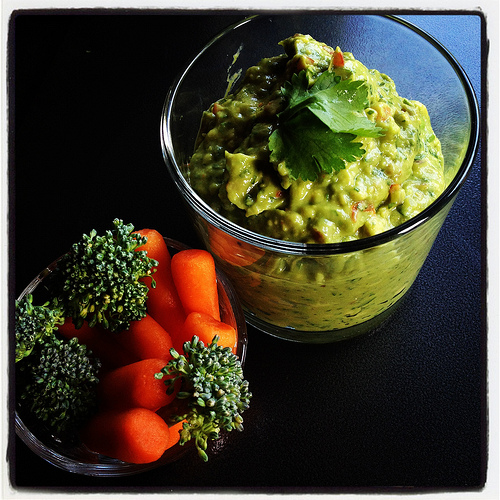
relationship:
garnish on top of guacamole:
[252, 64, 399, 185] [200, 27, 445, 335]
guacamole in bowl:
[188, 34, 448, 336] [138, 16, 482, 347]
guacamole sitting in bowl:
[188, 34, 448, 344] [138, 16, 482, 347]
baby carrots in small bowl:
[100, 223, 212, 465] [13, 227, 249, 487]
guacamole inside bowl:
[188, 34, 448, 336] [160, 9, 482, 346]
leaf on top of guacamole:
[270, 114, 360, 179] [200, 27, 445, 335]